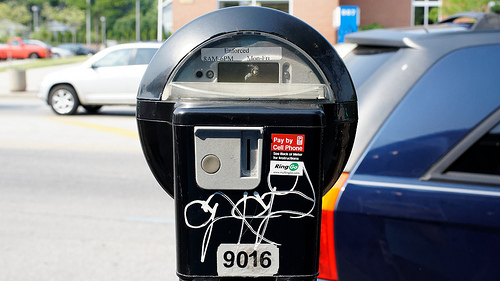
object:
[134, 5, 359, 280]
meter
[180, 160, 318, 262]
graffiti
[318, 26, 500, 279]
car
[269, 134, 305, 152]
pay by cell phone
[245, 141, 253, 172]
coin slot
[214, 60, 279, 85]
display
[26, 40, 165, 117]
car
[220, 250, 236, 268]
number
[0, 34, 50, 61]
car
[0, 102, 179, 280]
road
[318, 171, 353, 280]
tail light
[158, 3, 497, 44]
building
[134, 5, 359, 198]
circle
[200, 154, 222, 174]
button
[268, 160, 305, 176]
sticker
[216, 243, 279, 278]
identification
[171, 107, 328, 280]
box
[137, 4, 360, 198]
top of meter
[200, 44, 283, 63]
label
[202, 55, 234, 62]
times